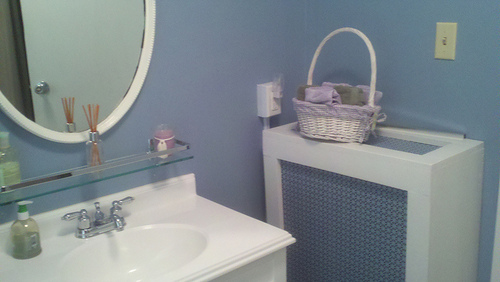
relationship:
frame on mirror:
[0, 2, 159, 146] [2, 0, 144, 131]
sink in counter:
[56, 223, 207, 280] [2, 171, 296, 280]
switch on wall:
[433, 20, 459, 63] [307, 2, 497, 280]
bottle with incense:
[82, 127, 105, 168] [81, 97, 103, 164]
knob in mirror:
[32, 78, 51, 96] [2, 0, 144, 131]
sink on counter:
[56, 223, 207, 280] [2, 171, 296, 280]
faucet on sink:
[60, 192, 133, 237] [56, 223, 207, 280]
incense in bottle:
[81, 97, 103, 164] [82, 127, 105, 168]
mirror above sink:
[2, 0, 144, 131] [56, 223, 207, 280]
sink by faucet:
[56, 223, 207, 280] [60, 192, 133, 237]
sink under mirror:
[56, 223, 207, 280] [2, 0, 144, 131]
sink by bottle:
[56, 223, 207, 280] [82, 127, 105, 168]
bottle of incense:
[82, 127, 105, 168] [81, 97, 103, 164]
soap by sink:
[7, 195, 44, 259] [56, 223, 207, 280]